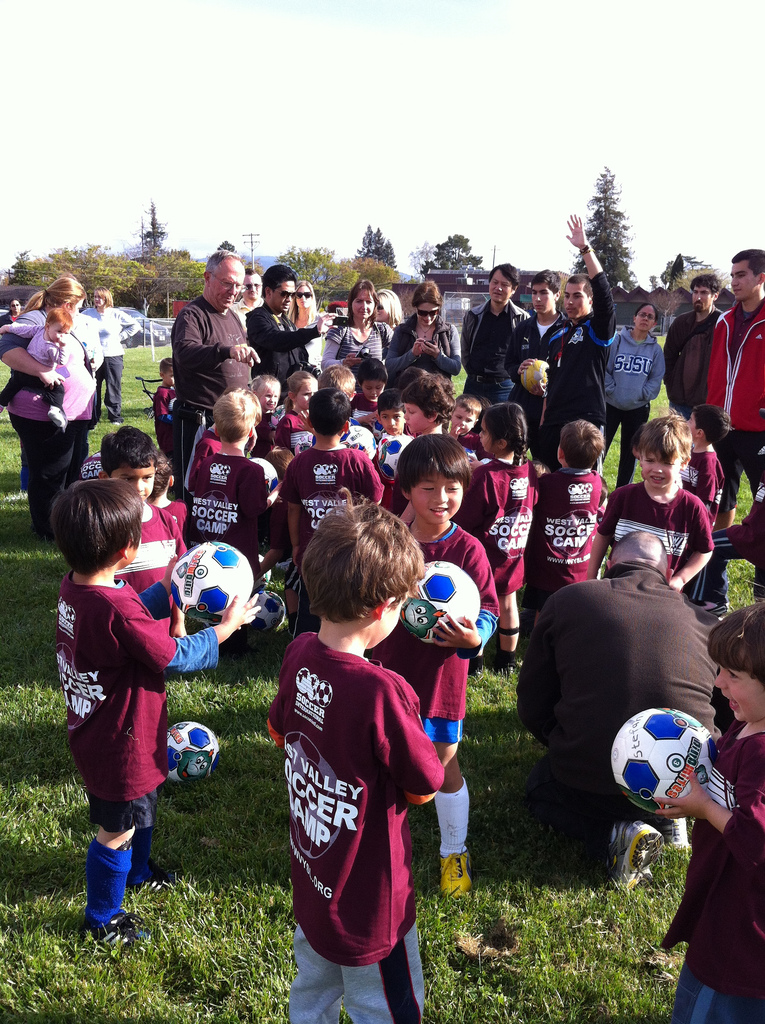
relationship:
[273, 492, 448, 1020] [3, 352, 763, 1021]
child standing on field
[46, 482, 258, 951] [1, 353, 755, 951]
child standing on field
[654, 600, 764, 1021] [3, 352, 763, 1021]
child standing on field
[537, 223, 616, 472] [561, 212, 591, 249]
man raising hand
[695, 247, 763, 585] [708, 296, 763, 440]
man wearing coat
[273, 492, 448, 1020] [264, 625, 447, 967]
child wearing jersey